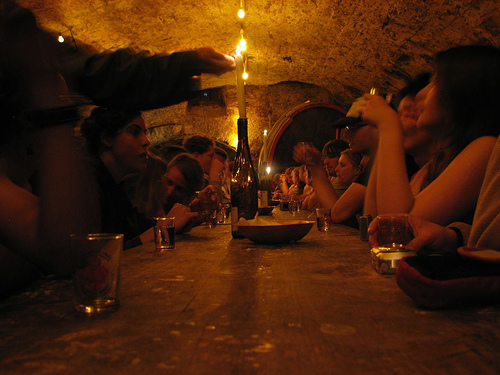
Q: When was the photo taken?
A: Night time.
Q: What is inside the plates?
A: Food.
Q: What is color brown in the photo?
A: The table.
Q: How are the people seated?
A: Next to each other.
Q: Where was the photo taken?
A: In a restaurant.